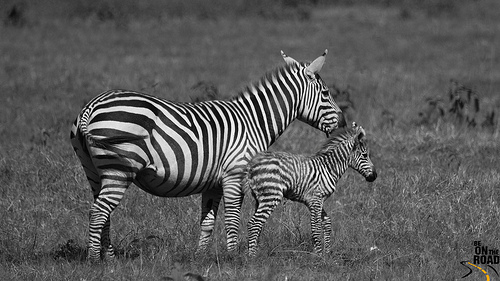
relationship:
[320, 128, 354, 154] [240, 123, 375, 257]
mane on zebra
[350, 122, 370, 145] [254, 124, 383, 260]
ear on zebra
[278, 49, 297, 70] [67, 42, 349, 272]
ear on zebra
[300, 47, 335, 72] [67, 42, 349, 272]
ear on zebra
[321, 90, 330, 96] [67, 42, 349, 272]
eye on zebra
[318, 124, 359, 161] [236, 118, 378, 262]
fur on baby zebra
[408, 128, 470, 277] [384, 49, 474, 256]
grass on ground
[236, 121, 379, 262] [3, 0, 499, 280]
baby zebra on grass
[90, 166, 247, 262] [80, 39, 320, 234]
legs on zebra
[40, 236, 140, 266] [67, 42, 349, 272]
shadow of zebra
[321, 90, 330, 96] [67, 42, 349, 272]
eye of zebra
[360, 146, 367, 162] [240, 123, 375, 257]
eye of zebra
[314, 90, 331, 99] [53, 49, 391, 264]
eye of zebra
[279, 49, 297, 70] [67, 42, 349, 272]
ear of zebra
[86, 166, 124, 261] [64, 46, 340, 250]
leg of zebra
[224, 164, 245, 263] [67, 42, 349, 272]
leg of zebra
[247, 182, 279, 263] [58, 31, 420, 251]
leg of zebra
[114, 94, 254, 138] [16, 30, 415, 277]
back of zebra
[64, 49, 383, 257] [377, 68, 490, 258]
zebras in grass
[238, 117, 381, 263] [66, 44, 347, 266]
baby next to adult